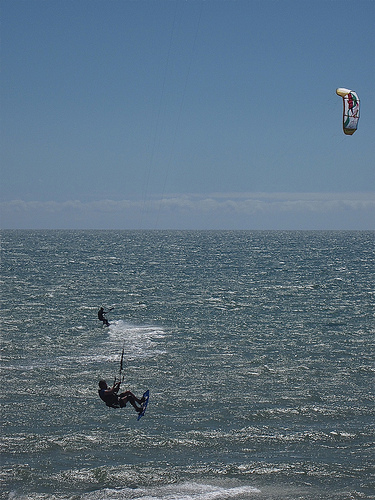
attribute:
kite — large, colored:
[335, 88, 360, 135]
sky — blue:
[0, 0, 373, 229]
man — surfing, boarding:
[96, 377, 152, 422]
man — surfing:
[96, 305, 116, 328]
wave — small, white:
[84, 481, 266, 500]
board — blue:
[135, 389, 149, 421]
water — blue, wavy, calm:
[0, 229, 374, 499]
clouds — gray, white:
[2, 189, 374, 232]